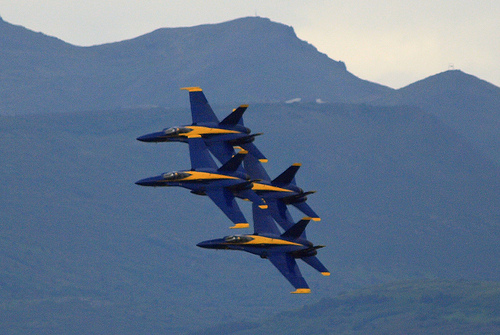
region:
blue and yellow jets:
[122, 68, 329, 315]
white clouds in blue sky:
[355, 19, 403, 49]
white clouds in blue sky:
[55, 9, 116, 36]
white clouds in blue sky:
[407, 23, 471, 60]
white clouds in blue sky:
[337, 8, 477, 60]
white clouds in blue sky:
[365, 16, 412, 50]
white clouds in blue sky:
[327, 21, 378, 55]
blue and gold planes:
[101, 70, 328, 315]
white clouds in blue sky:
[412, 19, 454, 59]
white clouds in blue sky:
[378, 22, 436, 52]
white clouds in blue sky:
[290, 13, 345, 54]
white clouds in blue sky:
[435, 12, 482, 64]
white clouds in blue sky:
[412, 11, 474, 91]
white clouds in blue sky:
[320, 2, 384, 72]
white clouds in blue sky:
[350, 28, 398, 93]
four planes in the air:
[102, 67, 357, 334]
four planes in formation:
[109, 68, 353, 333]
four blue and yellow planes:
[115, 47, 397, 329]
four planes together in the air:
[113, 42, 348, 294]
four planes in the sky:
[104, 56, 394, 319]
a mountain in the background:
[6, 15, 496, 217]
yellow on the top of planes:
[153, 81, 338, 287]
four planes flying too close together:
[116, 49, 448, 328]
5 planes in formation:
[136, 84, 328, 293]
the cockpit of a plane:
[167, 168, 179, 178]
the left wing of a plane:
[179, 83, 216, 123]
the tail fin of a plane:
[296, 187, 312, 202]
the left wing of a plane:
[269, 252, 311, 296]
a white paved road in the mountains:
[286, 91, 322, 105]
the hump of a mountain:
[139, 0, 351, 85]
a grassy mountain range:
[0, 11, 498, 326]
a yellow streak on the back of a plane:
[183, 167, 239, 185]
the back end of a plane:
[242, 187, 269, 212]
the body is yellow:
[256, 236, 277, 243]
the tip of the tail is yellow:
[291, 161, 302, 171]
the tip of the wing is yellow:
[231, 222, 253, 229]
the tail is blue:
[281, 172, 292, 183]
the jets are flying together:
[190, 120, 305, 253]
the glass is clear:
[166, 170, 178, 181]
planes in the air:
[96, 51, 397, 303]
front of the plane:
[171, 227, 232, 271]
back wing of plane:
[281, 213, 340, 282]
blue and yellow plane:
[173, 206, 340, 304]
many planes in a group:
[117, 100, 376, 330]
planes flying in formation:
[81, 93, 366, 310]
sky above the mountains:
[358, 12, 449, 68]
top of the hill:
[153, 8, 334, 63]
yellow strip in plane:
[241, 218, 312, 268]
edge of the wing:
[168, 64, 222, 114]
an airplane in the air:
[205, 216, 313, 271]